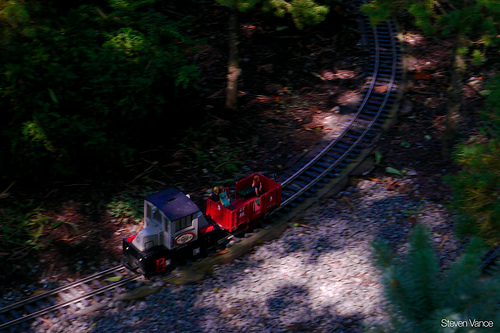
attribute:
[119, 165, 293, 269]
train — toy, grey, red, small, purple, blue, silver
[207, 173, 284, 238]
car — red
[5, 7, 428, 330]
tracks — curved, long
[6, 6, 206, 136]
leaves — green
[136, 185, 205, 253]
cabin — purple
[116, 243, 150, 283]
bumper — green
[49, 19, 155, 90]
flower — green